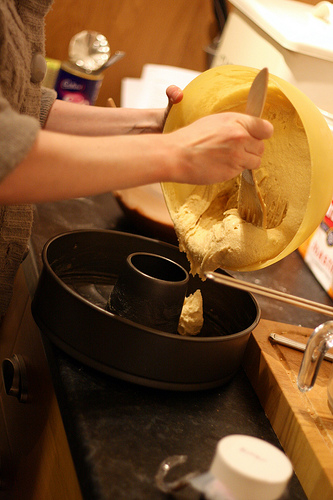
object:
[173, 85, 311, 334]
cake mixture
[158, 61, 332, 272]
mixing bowl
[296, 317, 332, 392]
handle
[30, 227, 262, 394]
cake tin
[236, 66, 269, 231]
spatula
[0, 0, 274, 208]
person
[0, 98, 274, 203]
arm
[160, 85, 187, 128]
left hand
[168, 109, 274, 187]
right hand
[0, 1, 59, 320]
sweater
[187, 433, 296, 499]
measuring cup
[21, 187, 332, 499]
counter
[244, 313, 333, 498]
chopping board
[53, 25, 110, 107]
frosting container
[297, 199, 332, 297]
bag of flour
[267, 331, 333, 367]
knife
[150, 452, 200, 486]
handle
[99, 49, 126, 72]
spoon